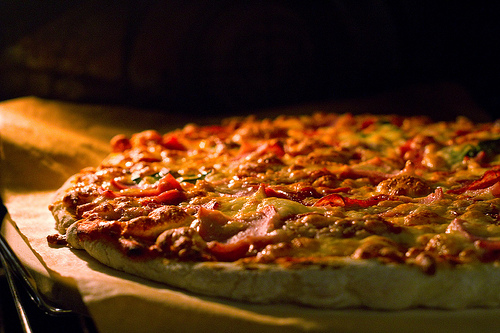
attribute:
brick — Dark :
[28, 23, 225, 95]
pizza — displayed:
[52, 110, 499, 325]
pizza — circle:
[31, 95, 498, 320]